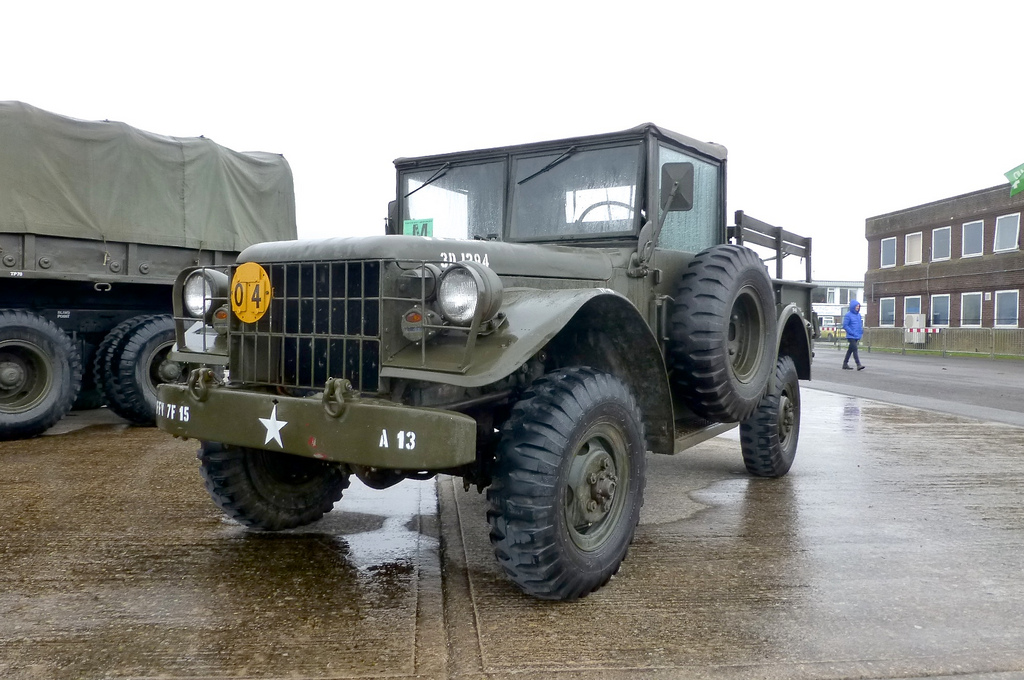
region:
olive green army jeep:
[168, 117, 799, 592]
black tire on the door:
[663, 225, 774, 413]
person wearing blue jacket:
[834, 291, 879, 364]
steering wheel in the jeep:
[572, 194, 629, 236]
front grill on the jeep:
[237, 245, 371, 381]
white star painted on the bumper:
[250, 409, 299, 449]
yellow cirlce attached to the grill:
[218, 256, 280, 323]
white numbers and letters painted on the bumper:
[151, 390, 421, 460]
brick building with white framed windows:
[854, 174, 1020, 331]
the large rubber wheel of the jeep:
[194, 437, 356, 527]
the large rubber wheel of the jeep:
[487, 363, 652, 594]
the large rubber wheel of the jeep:
[669, 238, 774, 412]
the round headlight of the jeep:
[182, 272, 218, 327]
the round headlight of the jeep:
[437, 257, 502, 327]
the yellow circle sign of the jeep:
[229, 257, 274, 319]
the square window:
[925, 219, 954, 262]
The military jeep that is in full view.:
[166, 129, 830, 601]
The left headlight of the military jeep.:
[175, 267, 221, 318]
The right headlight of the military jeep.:
[405, 251, 485, 325]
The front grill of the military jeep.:
[231, 255, 386, 404]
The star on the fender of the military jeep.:
[251, 401, 286, 447]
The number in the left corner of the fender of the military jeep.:
[157, 401, 197, 421]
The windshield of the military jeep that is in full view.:
[403, 143, 648, 227]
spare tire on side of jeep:
[667, 236, 789, 437]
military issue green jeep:
[144, 121, 841, 603]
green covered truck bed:
[0, 97, 296, 421]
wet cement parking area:
[23, 344, 1017, 677]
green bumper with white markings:
[146, 372, 491, 477]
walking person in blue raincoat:
[832, 294, 878, 378]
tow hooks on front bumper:
[171, 369, 369, 423]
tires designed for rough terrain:
[185, 364, 796, 599]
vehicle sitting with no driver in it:
[156, 123, 823, 585]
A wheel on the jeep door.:
[679, 241, 790, 403]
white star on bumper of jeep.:
[246, 398, 303, 457]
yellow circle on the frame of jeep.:
[218, 263, 294, 340]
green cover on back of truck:
[18, 94, 332, 268]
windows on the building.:
[884, 238, 1017, 265]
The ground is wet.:
[49, 475, 992, 673]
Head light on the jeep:
[432, 271, 490, 317]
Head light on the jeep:
[176, 278, 218, 321]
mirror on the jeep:
[657, 146, 692, 220]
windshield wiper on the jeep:
[506, 138, 583, 186]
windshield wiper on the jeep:
[400, 161, 473, 200]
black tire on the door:
[676, 247, 793, 399]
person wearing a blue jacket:
[847, 288, 874, 336]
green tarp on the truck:
[0, 82, 292, 251]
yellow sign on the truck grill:
[228, 262, 279, 311]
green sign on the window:
[397, 214, 430, 241]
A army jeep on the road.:
[158, 148, 839, 575]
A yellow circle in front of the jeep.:
[214, 255, 297, 326]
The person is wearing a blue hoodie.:
[838, 301, 859, 346]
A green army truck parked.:
[10, 95, 314, 415]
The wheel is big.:
[498, 377, 664, 587]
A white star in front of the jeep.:
[250, 395, 289, 449]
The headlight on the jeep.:
[411, 262, 511, 340]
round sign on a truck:
[230, 259, 273, 324]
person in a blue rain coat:
[840, 294, 864, 368]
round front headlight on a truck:
[442, 266, 471, 320]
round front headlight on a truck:
[185, 274, 211, 314]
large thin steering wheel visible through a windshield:
[578, 199, 632, 222]